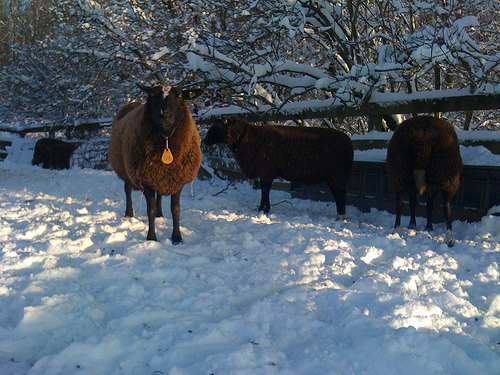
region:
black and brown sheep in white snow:
[24, 120, 72, 172]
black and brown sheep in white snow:
[105, 80, 200, 235]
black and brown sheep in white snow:
[208, 111, 366, 239]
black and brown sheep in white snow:
[377, 105, 489, 242]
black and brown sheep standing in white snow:
[117, 83, 202, 227]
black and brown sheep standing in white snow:
[217, 113, 359, 203]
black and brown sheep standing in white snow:
[377, 111, 468, 236]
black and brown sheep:
[101, 88, 203, 255]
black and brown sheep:
[189, 99, 359, 205]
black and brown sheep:
[374, 109, 485, 231]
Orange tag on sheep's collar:
[158, 128, 180, 173]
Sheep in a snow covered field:
[3, 91, 474, 285]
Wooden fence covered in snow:
[4, 84, 499, 214]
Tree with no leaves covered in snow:
[0, 0, 488, 132]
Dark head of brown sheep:
[134, 77, 197, 142]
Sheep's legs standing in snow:
[110, 181, 200, 248]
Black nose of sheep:
[153, 105, 177, 125]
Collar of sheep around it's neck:
[146, 126, 185, 141]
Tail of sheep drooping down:
[408, 138, 432, 205]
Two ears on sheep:
[132, 80, 209, 97]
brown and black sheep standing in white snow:
[108, 82, 200, 236]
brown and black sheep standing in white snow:
[210, 114, 350, 207]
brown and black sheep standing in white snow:
[382, 100, 462, 223]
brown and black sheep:
[107, 83, 201, 239]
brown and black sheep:
[216, 108, 361, 225]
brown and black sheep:
[375, 99, 464, 220]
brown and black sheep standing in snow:
[95, 74, 205, 239]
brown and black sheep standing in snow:
[207, 106, 361, 207]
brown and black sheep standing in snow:
[388, 105, 470, 227]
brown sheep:
[82, 82, 201, 257]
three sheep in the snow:
[75, 70, 445, 283]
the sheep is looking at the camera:
[131, 70, 191, 175]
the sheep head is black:
[117, 52, 222, 147]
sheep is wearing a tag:
[122, 130, 198, 175]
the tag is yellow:
[118, 126, 200, 189]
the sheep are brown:
[77, 66, 452, 274]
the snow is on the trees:
[172, 0, 407, 87]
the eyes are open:
[132, 77, 191, 111]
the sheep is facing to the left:
[192, 85, 373, 235]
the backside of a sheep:
[367, 85, 477, 261]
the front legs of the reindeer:
[143, 185, 188, 248]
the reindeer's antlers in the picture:
[138, 81, 220, 101]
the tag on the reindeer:
[156, 138, 183, 165]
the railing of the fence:
[205, 102, 499, 115]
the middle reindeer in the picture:
[209, 119, 359, 213]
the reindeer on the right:
[379, 114, 481, 239]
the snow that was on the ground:
[3, 157, 492, 372]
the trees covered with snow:
[66, 31, 477, 99]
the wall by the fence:
[22, 135, 229, 187]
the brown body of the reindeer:
[110, 108, 212, 200]